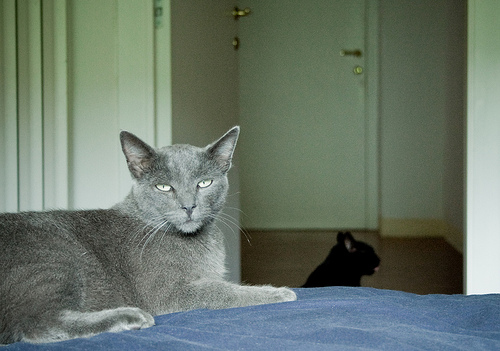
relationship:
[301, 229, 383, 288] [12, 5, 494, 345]
black cat in bedroom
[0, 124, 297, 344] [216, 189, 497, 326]
cat on bed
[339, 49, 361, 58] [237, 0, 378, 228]
handle on door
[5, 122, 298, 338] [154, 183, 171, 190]
cat has eye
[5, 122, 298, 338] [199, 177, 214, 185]
cat has eye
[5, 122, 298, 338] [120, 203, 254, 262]
cat has whiskers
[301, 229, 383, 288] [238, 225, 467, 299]
black cat on floor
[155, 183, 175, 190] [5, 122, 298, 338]
eye of cat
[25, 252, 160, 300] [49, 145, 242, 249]
fur on cat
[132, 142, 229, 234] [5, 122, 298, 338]
head of a cat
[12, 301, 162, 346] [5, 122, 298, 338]
cat's left/leg of a cat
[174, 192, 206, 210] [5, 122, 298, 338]
nose of cat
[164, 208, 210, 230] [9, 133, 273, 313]
mouth of cat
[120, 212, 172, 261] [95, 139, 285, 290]
whisker of cat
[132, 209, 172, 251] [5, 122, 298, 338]
whisker of cat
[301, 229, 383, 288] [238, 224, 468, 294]
black cat on ground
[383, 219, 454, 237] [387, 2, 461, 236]
wall trim on wall